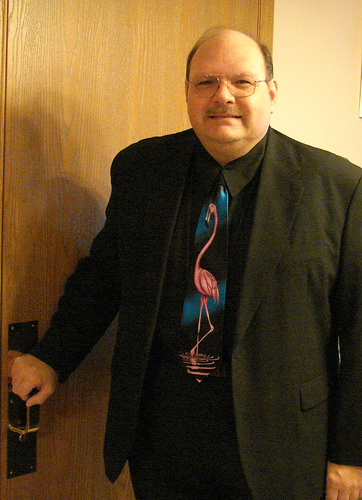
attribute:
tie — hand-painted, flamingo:
[175, 182, 230, 388]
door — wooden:
[0, 7, 267, 495]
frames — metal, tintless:
[193, 75, 257, 96]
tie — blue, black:
[182, 178, 234, 388]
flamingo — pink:
[188, 197, 220, 365]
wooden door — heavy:
[2, 2, 359, 498]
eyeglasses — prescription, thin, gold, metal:
[183, 71, 260, 101]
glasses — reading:
[188, 72, 267, 97]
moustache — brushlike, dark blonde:
[200, 104, 249, 115]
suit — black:
[24, 125, 361, 497]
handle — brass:
[9, 385, 41, 437]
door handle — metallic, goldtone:
[1, 316, 46, 485]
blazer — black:
[24, 126, 361, 498]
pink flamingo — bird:
[184, 196, 240, 369]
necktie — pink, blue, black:
[168, 171, 225, 387]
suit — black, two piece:
[49, 87, 359, 479]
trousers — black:
[126, 361, 252, 498]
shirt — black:
[155, 131, 269, 361]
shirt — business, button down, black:
[150, 129, 271, 456]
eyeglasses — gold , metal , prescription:
[187, 71, 267, 97]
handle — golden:
[6, 319, 39, 479]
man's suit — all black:
[117, 139, 348, 428]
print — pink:
[184, 200, 225, 384]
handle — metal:
[10, 356, 43, 442]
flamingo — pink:
[189, 201, 222, 356]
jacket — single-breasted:
[32, 126, 361, 498]